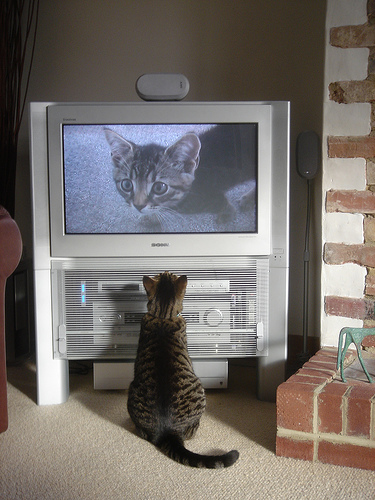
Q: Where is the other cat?
A: On the tv screen.